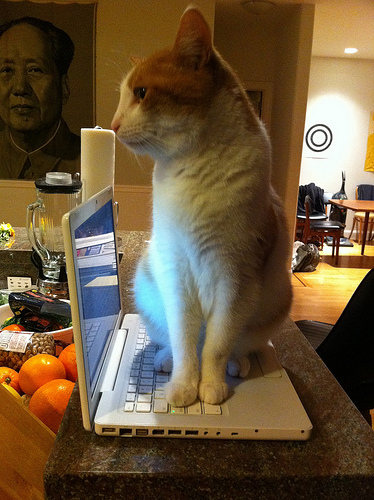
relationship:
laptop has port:
[55, 183, 316, 445] [98, 420, 122, 447]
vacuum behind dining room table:
[326, 166, 351, 246] [328, 191, 373, 259]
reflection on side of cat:
[126, 227, 196, 362] [109, 6, 297, 411]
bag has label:
[2, 327, 61, 376] [2, 329, 36, 355]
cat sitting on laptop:
[109, 6, 297, 411] [55, 183, 316, 445]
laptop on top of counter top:
[55, 183, 316, 445] [37, 310, 370, 500]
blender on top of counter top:
[7, 165, 86, 335] [37, 310, 370, 500]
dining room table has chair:
[328, 191, 373, 259] [302, 188, 347, 266]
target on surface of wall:
[302, 119, 336, 156] [312, 59, 372, 240]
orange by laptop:
[17, 351, 68, 398] [55, 183, 316, 445]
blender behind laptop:
[7, 165, 86, 335] [55, 183, 316, 445]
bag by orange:
[2, 327, 61, 376] [17, 351, 68, 398]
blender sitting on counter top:
[7, 165, 86, 335] [37, 310, 370, 500]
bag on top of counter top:
[2, 327, 61, 376] [37, 310, 370, 500]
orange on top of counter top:
[17, 351, 68, 398] [37, 310, 370, 500]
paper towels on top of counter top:
[76, 121, 119, 208] [37, 310, 370, 500]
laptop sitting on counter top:
[55, 183, 316, 445] [37, 310, 370, 500]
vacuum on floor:
[326, 166, 351, 246] [289, 239, 373, 325]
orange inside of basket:
[17, 351, 68, 398] [2, 375, 66, 499]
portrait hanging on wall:
[2, 2, 100, 182] [2, 4, 212, 236]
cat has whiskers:
[109, 6, 297, 411] [116, 112, 185, 166]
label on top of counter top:
[2, 329, 36, 355] [37, 310, 370, 500]